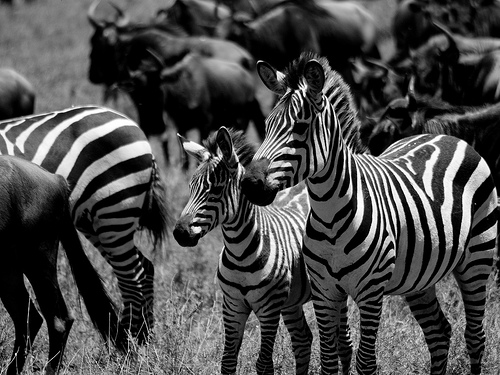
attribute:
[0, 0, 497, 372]
grass — dried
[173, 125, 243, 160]
ears — long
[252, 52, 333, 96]
ears — long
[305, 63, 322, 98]
ear — alert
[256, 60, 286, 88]
ear — alert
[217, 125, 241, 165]
ear — alert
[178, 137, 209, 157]
ear — alert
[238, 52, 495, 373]
zebra — black, white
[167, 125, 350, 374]
zebra — colt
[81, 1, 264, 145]
water buffalo — large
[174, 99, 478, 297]
zebra — baby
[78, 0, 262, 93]
wildebeest — brown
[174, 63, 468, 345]
zebra — black, white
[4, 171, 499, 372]
grass — dry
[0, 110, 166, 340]
zebra — white, black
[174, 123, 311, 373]
zebra — white, black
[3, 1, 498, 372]
animals — bunch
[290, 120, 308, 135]
eye — black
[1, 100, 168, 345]
stripes — black, white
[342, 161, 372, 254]
stripe — black, white 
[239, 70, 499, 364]
zebra — white, black, adult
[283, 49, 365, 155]
hair — tall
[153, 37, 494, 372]
zebras — baby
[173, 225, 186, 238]
tip — black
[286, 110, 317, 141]
eye — black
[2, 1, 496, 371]
field — grass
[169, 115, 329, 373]
zebra — black, white, baby